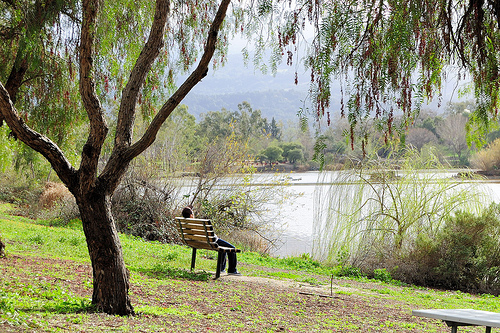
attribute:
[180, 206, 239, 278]
guy — looking, sitting, relaxing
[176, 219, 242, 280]
bench — wooden, brown, stone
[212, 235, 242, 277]
jeans — green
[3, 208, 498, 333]
ground — green, grassy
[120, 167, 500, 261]
water — calm, gray, several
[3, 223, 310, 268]
grass — green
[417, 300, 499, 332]
bench — gray, outdoors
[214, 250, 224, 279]
leg — black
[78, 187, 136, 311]
tree trunk — brown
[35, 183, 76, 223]
bush — brown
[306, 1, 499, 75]
branches — hanging, brown, green, dead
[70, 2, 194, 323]
tree — shading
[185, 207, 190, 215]
hair — brown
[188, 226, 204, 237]
slats — wooden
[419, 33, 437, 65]
blooms — purple